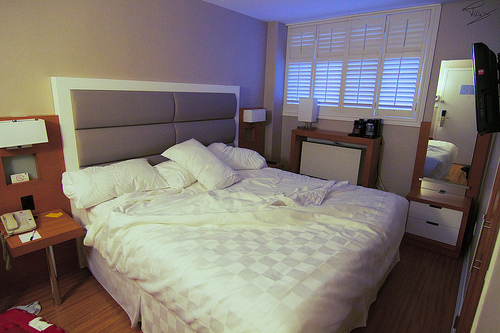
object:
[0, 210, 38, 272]
phone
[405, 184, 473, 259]
stand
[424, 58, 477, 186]
mirror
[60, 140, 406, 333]
bed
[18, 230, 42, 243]
paper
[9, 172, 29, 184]
card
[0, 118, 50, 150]
lamp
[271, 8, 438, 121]
window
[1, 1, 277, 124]
wall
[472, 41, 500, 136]
tv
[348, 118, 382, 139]
coffe maker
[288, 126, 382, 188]
table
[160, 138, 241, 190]
pillow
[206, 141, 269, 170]
pillow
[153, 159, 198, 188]
pillow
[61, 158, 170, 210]
pillow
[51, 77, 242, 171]
headboard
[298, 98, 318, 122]
shade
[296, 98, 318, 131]
lamp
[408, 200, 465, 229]
drawer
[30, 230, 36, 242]
pen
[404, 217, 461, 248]
drawer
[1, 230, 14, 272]
cord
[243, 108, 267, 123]
light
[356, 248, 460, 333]
floor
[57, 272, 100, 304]
shadow